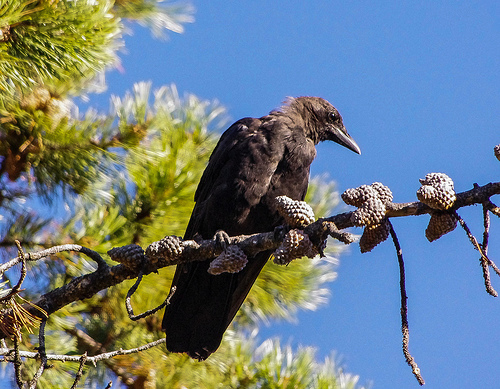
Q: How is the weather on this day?
A: It is clear.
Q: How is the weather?
A: It is clear.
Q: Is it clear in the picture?
A: Yes, it is clear.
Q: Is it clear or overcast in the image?
A: It is clear.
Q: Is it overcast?
A: No, it is clear.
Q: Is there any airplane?
A: No, there are no airplanes.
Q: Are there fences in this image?
A: No, there are no fences.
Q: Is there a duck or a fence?
A: No, there are no fences or ducks.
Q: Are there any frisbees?
A: No, there are no frisbees.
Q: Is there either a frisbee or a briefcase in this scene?
A: No, there are no frisbees or briefcases.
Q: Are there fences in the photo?
A: No, there are no fences.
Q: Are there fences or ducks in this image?
A: No, there are no fences or ducks.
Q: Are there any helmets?
A: No, there are no helmets.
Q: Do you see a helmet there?
A: No, there are no helmets.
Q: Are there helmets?
A: No, there are no helmets.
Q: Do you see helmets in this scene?
A: No, there are no helmets.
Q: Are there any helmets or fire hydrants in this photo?
A: No, there are no helmets or fire hydrants.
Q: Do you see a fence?
A: No, there are no fences.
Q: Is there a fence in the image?
A: No, there are no fences.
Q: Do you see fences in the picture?
A: No, there are no fences.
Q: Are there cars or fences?
A: No, there are no fences or cars.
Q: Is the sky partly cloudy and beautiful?
A: No, the sky is beautiful but clear.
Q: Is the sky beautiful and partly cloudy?
A: No, the sky is beautiful but clear.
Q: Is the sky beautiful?
A: Yes, the sky is beautiful.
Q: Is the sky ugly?
A: No, the sky is beautiful.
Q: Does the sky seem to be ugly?
A: No, the sky is beautiful.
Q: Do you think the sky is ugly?
A: No, the sky is beautiful.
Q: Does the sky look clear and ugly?
A: No, the sky is clear but beautiful.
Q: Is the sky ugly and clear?
A: No, the sky is clear but beautiful.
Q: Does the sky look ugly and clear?
A: No, the sky is clear but beautiful.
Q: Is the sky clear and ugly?
A: No, the sky is clear but beautiful.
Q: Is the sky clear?
A: Yes, the sky is clear.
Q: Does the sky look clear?
A: Yes, the sky is clear.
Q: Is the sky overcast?
A: No, the sky is clear.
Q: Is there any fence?
A: No, there are no fences.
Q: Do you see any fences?
A: No, there are no fences.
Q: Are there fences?
A: No, there are no fences.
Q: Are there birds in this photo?
A: Yes, there is a bird.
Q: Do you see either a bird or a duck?
A: Yes, there is a bird.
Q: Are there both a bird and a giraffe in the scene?
A: No, there is a bird but no giraffes.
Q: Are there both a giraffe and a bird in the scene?
A: No, there is a bird but no giraffes.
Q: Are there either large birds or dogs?
A: Yes, there is a large bird.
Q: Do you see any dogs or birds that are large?
A: Yes, the bird is large.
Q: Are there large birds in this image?
A: Yes, there is a large bird.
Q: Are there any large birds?
A: Yes, there is a large bird.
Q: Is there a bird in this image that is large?
A: Yes, there is a bird that is large.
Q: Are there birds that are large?
A: Yes, there is a bird that is large.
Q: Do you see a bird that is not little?
A: Yes, there is a large bird.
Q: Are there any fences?
A: No, there are no fences.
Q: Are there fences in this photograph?
A: No, there are no fences.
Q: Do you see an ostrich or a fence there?
A: No, there are no fences or ostriches.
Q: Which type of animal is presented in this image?
A: The animal is a bird.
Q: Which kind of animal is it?
A: The animal is a bird.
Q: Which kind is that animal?
A: That is a bird.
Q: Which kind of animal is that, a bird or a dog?
A: That is a bird.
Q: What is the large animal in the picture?
A: The animal is a bird.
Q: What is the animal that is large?
A: The animal is a bird.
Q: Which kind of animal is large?
A: The animal is a bird.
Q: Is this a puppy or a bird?
A: This is a bird.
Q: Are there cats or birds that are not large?
A: No, there is a bird but it is large.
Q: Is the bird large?
A: Yes, the bird is large.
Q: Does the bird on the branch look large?
A: Yes, the bird is large.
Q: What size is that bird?
A: The bird is large.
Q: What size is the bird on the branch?
A: The bird is large.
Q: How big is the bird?
A: The bird is large.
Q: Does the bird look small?
A: No, the bird is large.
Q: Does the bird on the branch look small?
A: No, the bird is large.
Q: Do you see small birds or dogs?
A: No, there is a bird but it is large.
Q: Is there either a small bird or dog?
A: No, there is a bird but it is large.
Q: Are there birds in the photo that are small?
A: No, there is a bird but it is large.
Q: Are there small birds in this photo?
A: No, there is a bird but it is large.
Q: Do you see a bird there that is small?
A: No, there is a bird but it is large.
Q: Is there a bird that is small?
A: No, there is a bird but it is large.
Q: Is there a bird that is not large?
A: No, there is a bird but it is large.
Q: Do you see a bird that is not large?
A: No, there is a bird but it is large.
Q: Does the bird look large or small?
A: The bird is large.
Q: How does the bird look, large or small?
A: The bird is large.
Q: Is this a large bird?
A: Yes, this is a large bird.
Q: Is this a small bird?
A: No, this is a large bird.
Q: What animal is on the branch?
A: The bird is on the branch.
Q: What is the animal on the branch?
A: The animal is a bird.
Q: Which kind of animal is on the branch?
A: The animal is a bird.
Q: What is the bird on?
A: The bird is on the branch.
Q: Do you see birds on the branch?
A: Yes, there is a bird on the branch.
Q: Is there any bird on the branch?
A: Yes, there is a bird on the branch.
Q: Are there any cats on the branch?
A: No, there is a bird on the branch.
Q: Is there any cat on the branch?
A: No, there is a bird on the branch.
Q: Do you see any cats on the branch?
A: No, there is a bird on the branch.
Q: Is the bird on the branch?
A: Yes, the bird is on the branch.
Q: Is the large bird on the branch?
A: Yes, the bird is on the branch.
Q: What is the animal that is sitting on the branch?
A: The animal is a bird.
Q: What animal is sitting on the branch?
A: The animal is a bird.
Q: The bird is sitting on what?
A: The bird is sitting on the branch.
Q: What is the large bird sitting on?
A: The bird is sitting on the branch.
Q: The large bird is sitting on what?
A: The bird is sitting on the branch.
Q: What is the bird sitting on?
A: The bird is sitting on the branch.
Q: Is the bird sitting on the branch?
A: Yes, the bird is sitting on the branch.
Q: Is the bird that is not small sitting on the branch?
A: Yes, the bird is sitting on the branch.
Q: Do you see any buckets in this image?
A: No, there are no buckets.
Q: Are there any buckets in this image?
A: No, there are no buckets.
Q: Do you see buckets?
A: No, there are no buckets.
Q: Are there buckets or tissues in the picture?
A: No, there are no buckets or tissues.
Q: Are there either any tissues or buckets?
A: No, there are no buckets or tissues.